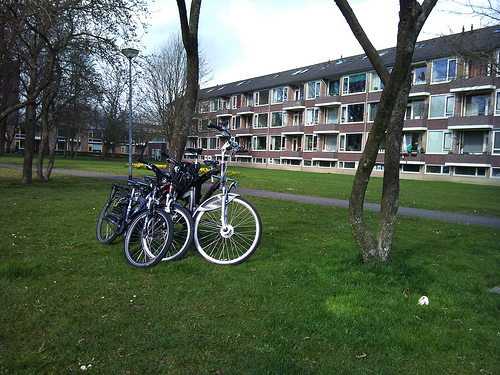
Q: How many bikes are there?
A: 4.